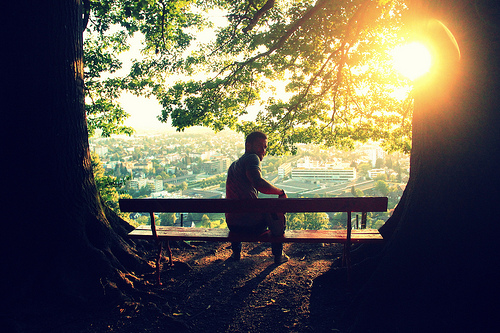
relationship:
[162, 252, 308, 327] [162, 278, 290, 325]
dirt on ground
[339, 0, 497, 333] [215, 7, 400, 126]
trees has branches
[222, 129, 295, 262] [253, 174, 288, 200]
man has hand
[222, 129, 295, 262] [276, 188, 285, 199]
man wearing wristwatch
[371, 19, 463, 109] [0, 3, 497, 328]
sunlight coming through trees